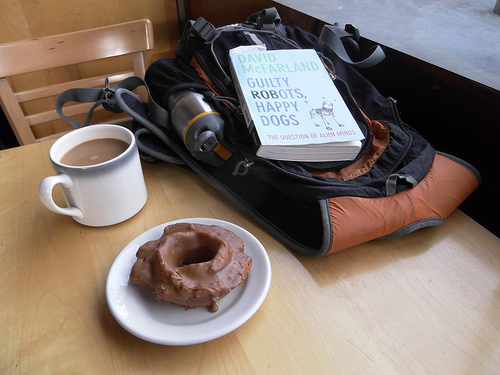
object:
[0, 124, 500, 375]
table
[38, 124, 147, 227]
cup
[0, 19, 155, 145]
chair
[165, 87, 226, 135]
plastic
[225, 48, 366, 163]
book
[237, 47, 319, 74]
author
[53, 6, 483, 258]
backpack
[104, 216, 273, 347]
plate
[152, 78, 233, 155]
bottle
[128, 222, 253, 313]
donut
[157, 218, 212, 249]
frosting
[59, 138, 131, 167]
coffee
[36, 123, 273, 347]
breakfast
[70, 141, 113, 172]
sauce